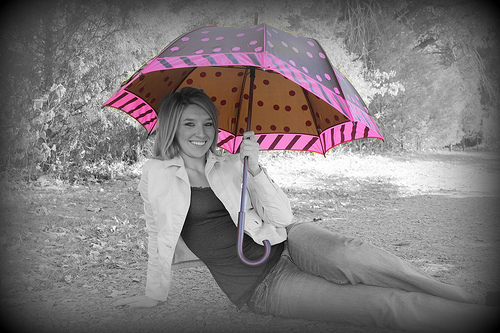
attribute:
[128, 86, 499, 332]
girl — sitting, smiling, seated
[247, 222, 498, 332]
legs — outstretched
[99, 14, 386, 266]
umbrella — pink, brown, black, open, opened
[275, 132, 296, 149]
stripes — brown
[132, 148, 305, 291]
jacket — white, cotton, light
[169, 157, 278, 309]
shirt — black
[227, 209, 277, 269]
handle — purple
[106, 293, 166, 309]
hand — resting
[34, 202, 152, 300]
leaves — fallen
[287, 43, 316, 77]
dots — polka, pink